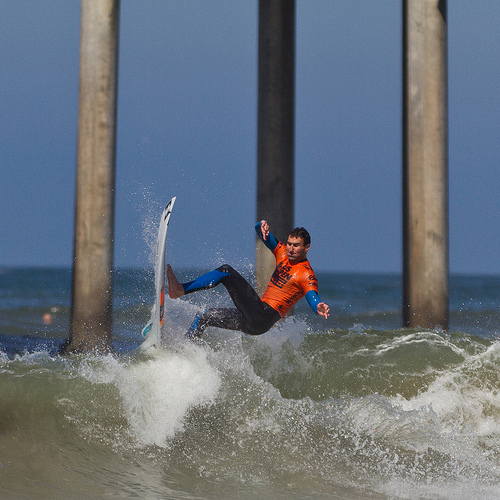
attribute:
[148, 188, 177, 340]
surfboard — surf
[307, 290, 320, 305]
sleeve — blue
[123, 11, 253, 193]
blue sky — clear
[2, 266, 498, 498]
water — white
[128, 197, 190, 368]
surf board — white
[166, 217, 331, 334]
man — surfing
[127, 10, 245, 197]
sky — clear , blue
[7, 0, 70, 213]
sky — clear , blue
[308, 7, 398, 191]
sky — clear 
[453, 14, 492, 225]
sky — clear , blue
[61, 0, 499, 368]
gray dock — based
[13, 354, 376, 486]
water — brown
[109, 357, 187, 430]
foam — white